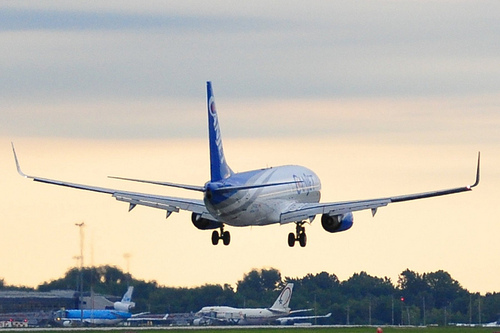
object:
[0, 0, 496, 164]
clouds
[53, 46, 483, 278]
plane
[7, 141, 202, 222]
wing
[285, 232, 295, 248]
wheels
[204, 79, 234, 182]
tail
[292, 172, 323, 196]
logo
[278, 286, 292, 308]
circle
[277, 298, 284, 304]
star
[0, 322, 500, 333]
ground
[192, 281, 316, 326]
airplanes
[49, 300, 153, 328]
airplanes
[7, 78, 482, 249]
planes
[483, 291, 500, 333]
trees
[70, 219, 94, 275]
towers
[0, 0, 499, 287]
sky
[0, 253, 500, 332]
airport